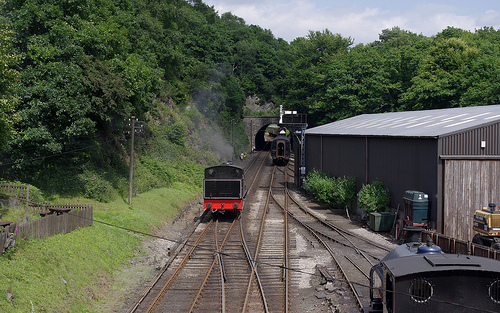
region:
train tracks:
[210, 240, 272, 310]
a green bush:
[77, 58, 149, 118]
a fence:
[36, 215, 63, 237]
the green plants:
[315, 174, 356, 206]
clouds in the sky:
[303, 6, 388, 28]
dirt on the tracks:
[302, 288, 315, 311]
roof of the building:
[354, 110, 467, 138]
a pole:
[121, 144, 140, 207]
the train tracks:
[318, 213, 358, 263]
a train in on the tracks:
[199, 167, 252, 216]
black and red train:
[210, 138, 274, 219]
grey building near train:
[289, 96, 496, 217]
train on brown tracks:
[179, 203, 346, 312]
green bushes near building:
[301, 164, 385, 233]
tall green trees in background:
[19, 0, 492, 167]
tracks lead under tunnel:
[229, 106, 305, 153]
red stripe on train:
[205, 186, 243, 218]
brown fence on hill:
[8, 201, 98, 239]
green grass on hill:
[29, 169, 174, 284]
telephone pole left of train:
[114, 113, 150, 211]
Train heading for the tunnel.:
[249, 117, 295, 158]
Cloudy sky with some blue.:
[188, 0, 498, 51]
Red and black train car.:
[202, 162, 244, 220]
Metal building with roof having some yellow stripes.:
[297, 102, 497, 238]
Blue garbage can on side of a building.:
[402, 186, 439, 244]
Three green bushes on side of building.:
[300, 165, 394, 221]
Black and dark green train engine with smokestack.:
[366, 224, 498, 311]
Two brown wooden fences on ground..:
[3, 181, 95, 253]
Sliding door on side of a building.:
[440, 152, 497, 251]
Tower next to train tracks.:
[278, 105, 311, 183]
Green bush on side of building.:
[357, 173, 402, 233]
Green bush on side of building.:
[308, 173, 360, 213]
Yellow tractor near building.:
[472, 193, 493, 217]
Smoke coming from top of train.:
[205, 118, 261, 175]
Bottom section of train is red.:
[195, 198, 244, 213]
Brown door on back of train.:
[266, 115, 297, 187]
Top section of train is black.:
[204, 167, 245, 198]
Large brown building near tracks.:
[313, 124, 486, 188]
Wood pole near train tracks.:
[108, 110, 145, 211]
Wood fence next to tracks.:
[16, 201, 105, 246]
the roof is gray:
[314, 92, 471, 172]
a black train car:
[188, 158, 270, 229]